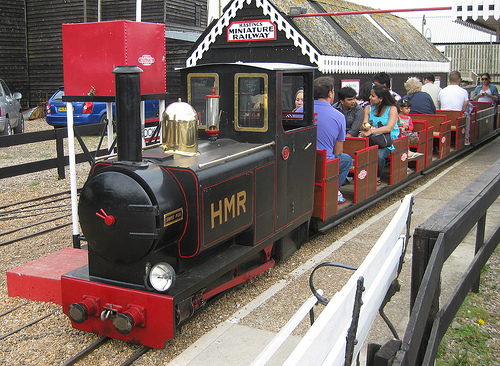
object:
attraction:
[63, 59, 500, 347]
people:
[288, 72, 500, 204]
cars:
[312, 98, 500, 235]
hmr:
[210, 190, 247, 229]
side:
[193, 111, 323, 321]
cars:
[0, 78, 162, 141]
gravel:
[6, 94, 499, 354]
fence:
[0, 104, 163, 180]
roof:
[181, 0, 453, 74]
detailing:
[316, 53, 450, 75]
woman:
[360, 84, 402, 187]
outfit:
[358, 102, 399, 143]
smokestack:
[109, 62, 146, 162]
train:
[53, 52, 500, 354]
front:
[54, 144, 188, 353]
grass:
[428, 236, 500, 366]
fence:
[357, 158, 499, 366]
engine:
[48, 52, 314, 352]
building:
[172, 0, 460, 144]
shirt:
[287, 101, 350, 162]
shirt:
[366, 100, 403, 153]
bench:
[239, 191, 413, 366]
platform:
[4, 244, 89, 306]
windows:
[184, 68, 271, 133]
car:
[42, 85, 166, 136]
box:
[58, 18, 170, 100]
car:
[310, 117, 409, 237]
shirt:
[396, 111, 413, 135]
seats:
[312, 96, 500, 232]